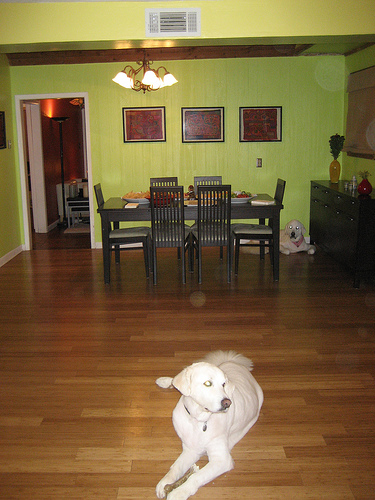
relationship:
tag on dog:
[203, 424, 209, 432] [155, 349, 264, 499]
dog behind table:
[242, 221, 318, 257] [97, 196, 282, 284]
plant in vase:
[329, 135, 345, 158] [330, 159, 342, 184]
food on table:
[126, 190, 258, 213] [97, 196, 282, 284]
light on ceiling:
[110, 55, 175, 97] [4, 36, 370, 68]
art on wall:
[120, 105, 283, 145] [9, 55, 354, 248]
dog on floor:
[155, 349, 264, 499] [2, 249, 373, 498]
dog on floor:
[242, 221, 318, 257] [2, 249, 373, 498]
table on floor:
[97, 196, 282, 284] [2, 249, 373, 498]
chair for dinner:
[92, 183, 150, 282] [124, 189, 254, 206]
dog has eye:
[155, 349, 264, 499] [203, 380, 211, 390]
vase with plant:
[330, 159, 342, 184] [329, 135, 345, 158]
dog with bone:
[155, 349, 264, 499] [162, 465, 202, 494]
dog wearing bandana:
[242, 221, 318, 257] [295, 238, 307, 247]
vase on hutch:
[330, 159, 342, 184] [308, 180, 372, 288]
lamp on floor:
[52, 112, 69, 227] [2, 249, 373, 498]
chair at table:
[92, 183, 150, 282] [97, 196, 282, 284]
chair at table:
[150, 186, 188, 281] [97, 196, 282, 284]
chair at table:
[151, 177, 183, 196] [97, 196, 282, 284]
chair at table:
[192, 176, 227, 190] [97, 196, 282, 284]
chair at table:
[231, 180, 288, 274] [97, 196, 282, 284]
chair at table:
[194, 186, 228, 281] [97, 196, 282, 284]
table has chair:
[97, 196, 282, 284] [92, 183, 150, 282]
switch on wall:
[255, 157, 263, 171] [9, 55, 354, 248]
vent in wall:
[144, 13, 201, 35] [9, 55, 354, 248]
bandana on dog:
[295, 238, 307, 247] [155, 349, 264, 499]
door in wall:
[17, 92, 96, 250] [9, 55, 354, 248]